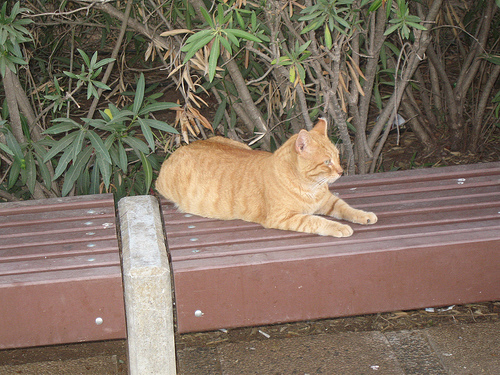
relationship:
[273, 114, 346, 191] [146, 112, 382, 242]
head of a cat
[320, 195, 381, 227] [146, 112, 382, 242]
leg of a cat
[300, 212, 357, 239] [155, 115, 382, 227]
leg of a cat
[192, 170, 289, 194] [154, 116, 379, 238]
fur of a cat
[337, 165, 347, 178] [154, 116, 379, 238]
nose of a cat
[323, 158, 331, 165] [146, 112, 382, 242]
cateye on cat